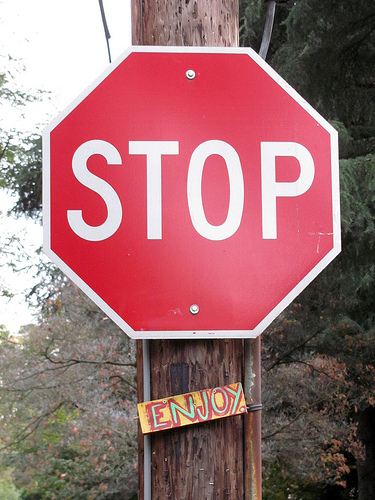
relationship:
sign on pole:
[40, 43, 344, 338] [129, 2, 270, 498]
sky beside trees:
[3, 12, 117, 323] [4, 6, 375, 494]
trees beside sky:
[4, 6, 375, 494] [3, 12, 117, 323]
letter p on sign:
[257, 137, 316, 244] [40, 43, 344, 338]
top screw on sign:
[182, 66, 198, 83] [40, 43, 344, 338]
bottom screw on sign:
[183, 298, 204, 315] [40, 43, 344, 338]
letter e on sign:
[148, 400, 172, 428] [40, 43, 344, 338]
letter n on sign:
[167, 391, 199, 423] [40, 43, 344, 338]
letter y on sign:
[223, 380, 249, 414] [40, 43, 344, 338]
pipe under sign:
[245, 331, 261, 497] [40, 43, 344, 338]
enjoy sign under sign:
[136, 381, 248, 434] [41, 44, 342, 337]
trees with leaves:
[4, 6, 375, 494] [281, 7, 355, 90]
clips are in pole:
[242, 398, 266, 417] [129, 2, 270, 498]